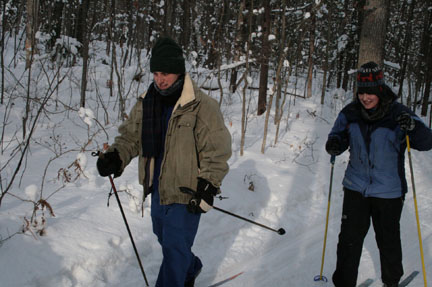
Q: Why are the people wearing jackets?
A: Cold.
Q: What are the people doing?
A: Skiing.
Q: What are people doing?
A: Skiing.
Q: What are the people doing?
A: Cross country skiing.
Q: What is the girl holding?
A: Yellow ski poles.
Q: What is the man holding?
A: Black ski poles.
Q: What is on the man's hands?
A: Black and white ski gloves.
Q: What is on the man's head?
A: A black knitted cap.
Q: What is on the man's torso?
A: A brown jacket.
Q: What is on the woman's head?
A: A multicolored knitted cap.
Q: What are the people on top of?
A: Snow.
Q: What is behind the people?
A: Trees and branches covered in snow.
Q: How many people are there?
A: Two.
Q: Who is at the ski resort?
A: Man and lady.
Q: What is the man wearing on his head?
A: Hat.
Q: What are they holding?
A: Ski sticks.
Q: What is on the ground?
A: Snow.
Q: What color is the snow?
A: White.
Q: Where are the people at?
A: Forest.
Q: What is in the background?
A: Trees.